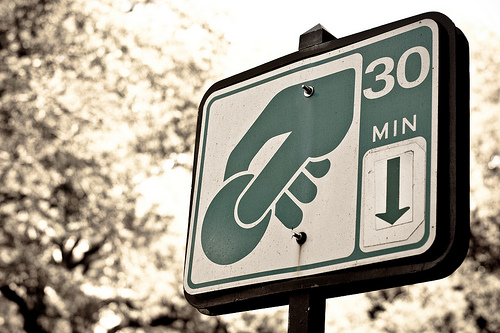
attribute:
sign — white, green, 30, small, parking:
[178, 12, 453, 307]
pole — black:
[287, 279, 327, 327]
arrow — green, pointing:
[357, 147, 426, 242]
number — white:
[312, 46, 417, 122]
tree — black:
[54, 67, 147, 193]